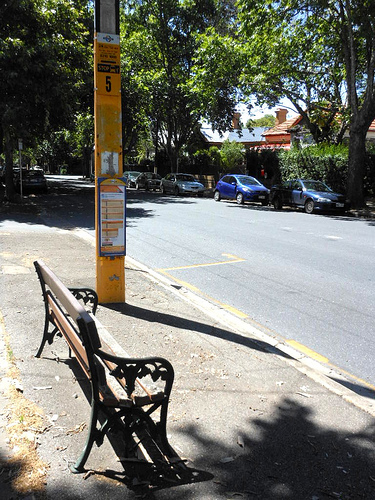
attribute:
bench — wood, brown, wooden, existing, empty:
[23, 256, 187, 478]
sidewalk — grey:
[2, 192, 372, 499]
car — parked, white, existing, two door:
[263, 175, 351, 217]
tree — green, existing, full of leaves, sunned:
[231, 1, 374, 208]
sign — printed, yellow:
[93, 32, 121, 100]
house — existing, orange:
[265, 90, 372, 152]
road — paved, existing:
[37, 168, 374, 383]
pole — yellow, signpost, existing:
[86, 3, 136, 312]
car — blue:
[210, 170, 270, 207]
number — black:
[101, 72, 115, 95]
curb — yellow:
[150, 266, 374, 410]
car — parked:
[14, 165, 50, 195]